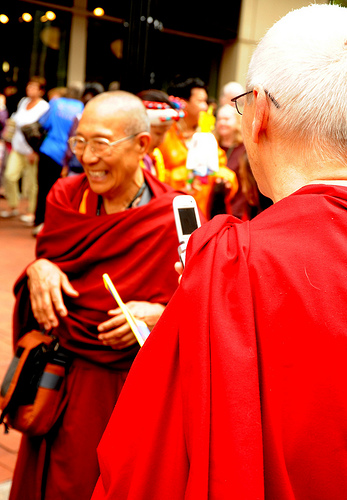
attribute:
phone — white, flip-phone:
[169, 192, 203, 266]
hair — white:
[248, 5, 346, 147]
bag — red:
[3, 333, 70, 432]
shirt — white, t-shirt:
[11, 99, 43, 154]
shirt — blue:
[40, 96, 83, 163]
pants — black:
[33, 147, 63, 223]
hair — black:
[168, 74, 207, 103]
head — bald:
[72, 88, 148, 193]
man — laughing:
[19, 92, 195, 500]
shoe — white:
[0, 206, 15, 220]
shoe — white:
[18, 212, 35, 226]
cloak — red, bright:
[91, 189, 344, 499]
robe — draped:
[14, 170, 172, 499]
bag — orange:
[3, 320, 79, 435]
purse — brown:
[22, 122, 48, 149]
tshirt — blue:
[37, 96, 83, 166]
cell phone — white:
[173, 194, 201, 263]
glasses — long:
[65, 131, 136, 153]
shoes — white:
[1, 209, 37, 223]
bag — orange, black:
[0, 328, 72, 436]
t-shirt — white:
[9, 96, 51, 155]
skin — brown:
[68, 89, 152, 214]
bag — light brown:
[1, 120, 16, 143]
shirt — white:
[8, 95, 49, 153]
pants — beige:
[2, 148, 39, 211]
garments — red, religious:
[40, 168, 346, 370]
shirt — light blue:
[36, 96, 82, 166]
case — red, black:
[0, 327, 74, 439]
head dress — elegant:
[138, 93, 186, 129]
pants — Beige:
[3, 149, 37, 212]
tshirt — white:
[10, 97, 49, 153]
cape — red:
[5, 154, 191, 489]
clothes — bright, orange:
[177, 131, 260, 217]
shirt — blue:
[39, 98, 87, 164]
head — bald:
[66, 89, 151, 193]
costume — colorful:
[159, 125, 234, 216]